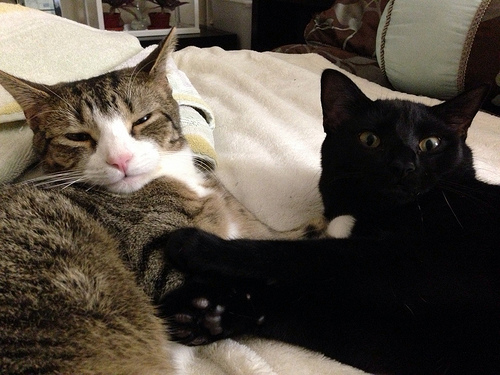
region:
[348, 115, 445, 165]
the cat has eyes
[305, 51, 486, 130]
the cat has ears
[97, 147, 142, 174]
the nose is pink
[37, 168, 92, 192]
the whiskers are white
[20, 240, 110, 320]
the cat is furry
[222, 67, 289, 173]
the blanket is tan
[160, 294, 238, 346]
the cat has a paw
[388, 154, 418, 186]
the nose is balck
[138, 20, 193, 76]
the cat has a right ear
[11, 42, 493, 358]
two cats are lying down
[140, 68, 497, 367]
black cat on white blanket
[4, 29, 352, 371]
gray, black, and white cat on white blanket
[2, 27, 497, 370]
two cats laying next to each other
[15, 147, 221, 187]
whiskers on a cat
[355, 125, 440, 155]
yellow eyes on black cat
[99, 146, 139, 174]
pink nose on cat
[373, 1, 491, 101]
pillow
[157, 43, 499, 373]
white fleece blanket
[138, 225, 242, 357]
front paws of black cat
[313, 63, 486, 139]
ears of black cat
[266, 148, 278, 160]
part of a cover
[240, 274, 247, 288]
leg of a cat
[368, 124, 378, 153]
eye of a cat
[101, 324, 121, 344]
body of a cat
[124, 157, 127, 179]
mouth of a cat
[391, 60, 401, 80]
part of a pillow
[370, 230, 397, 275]
body of a cat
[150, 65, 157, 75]
ear of a cat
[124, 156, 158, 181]
nose of a cat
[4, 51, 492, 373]
2 cats laying on bed together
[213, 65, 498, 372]
black cat laying on bed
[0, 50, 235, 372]
fuzzy striped cat on bed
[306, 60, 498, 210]
black cat's eyes are wide open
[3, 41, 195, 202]
tiger striped cat with squinted eyes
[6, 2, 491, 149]
white duvet cover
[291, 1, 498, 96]
brown comforter on bed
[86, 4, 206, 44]
bookshelf in background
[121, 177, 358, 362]
2 cats' paws touching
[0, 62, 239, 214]
cat with long whiskers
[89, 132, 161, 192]
A white muzzle of a cat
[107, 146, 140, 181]
Pink nose of a cat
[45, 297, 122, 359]
Grey fur of a cat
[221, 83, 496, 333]
A black cat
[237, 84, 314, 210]
A duvet on the bed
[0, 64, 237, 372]
A gray cat in the picture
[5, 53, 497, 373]
Cats on the bed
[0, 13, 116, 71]
A pillow on the bed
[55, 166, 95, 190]
White whiskers in the photo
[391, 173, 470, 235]
Cat black whiskers